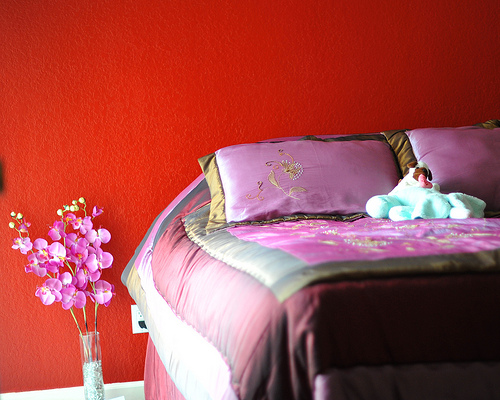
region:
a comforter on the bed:
[279, 232, 406, 294]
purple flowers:
[26, 231, 111, 298]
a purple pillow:
[222, 150, 367, 210]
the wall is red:
[69, 31, 190, 123]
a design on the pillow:
[260, 150, 326, 192]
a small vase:
[80, 333, 112, 398]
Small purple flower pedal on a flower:
[32, 281, 51, 303]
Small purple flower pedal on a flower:
[55, 291, 75, 309]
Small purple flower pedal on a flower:
[65, 289, 86, 306]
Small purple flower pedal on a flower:
[53, 270, 89, 288]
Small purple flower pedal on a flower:
[50, 242, 70, 267]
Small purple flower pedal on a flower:
[78, 213, 103, 238]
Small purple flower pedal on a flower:
[90, 249, 114, 270]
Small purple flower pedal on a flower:
[88, 279, 123, 304]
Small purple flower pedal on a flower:
[43, 225, 86, 241]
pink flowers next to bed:
[3, 197, 119, 334]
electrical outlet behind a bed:
[131, 299, 148, 334]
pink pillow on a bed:
[202, 132, 414, 228]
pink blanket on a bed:
[119, 164, 496, 398]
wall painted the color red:
[1, 3, 498, 393]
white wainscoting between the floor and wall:
[1, 380, 148, 397]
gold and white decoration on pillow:
[240, 147, 306, 202]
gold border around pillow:
[198, 148, 227, 228]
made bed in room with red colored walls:
[117, 119, 499, 399]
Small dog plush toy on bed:
[393, 159, 433, 188]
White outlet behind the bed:
[131, 303, 149, 333]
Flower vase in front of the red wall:
[8, 193, 116, 399]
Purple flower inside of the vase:
[50, 220, 68, 240]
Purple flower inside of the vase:
[68, 215, 95, 236]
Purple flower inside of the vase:
[86, 250, 112, 272]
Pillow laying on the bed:
[189, 129, 399, 231]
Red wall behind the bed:
[0, 0, 499, 394]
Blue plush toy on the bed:
[362, 185, 485, 220]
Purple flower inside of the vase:
[59, 286, 88, 309]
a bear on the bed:
[366, 160, 490, 227]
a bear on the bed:
[370, 149, 499, 233]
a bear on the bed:
[357, 155, 478, 232]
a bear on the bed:
[375, 150, 485, 235]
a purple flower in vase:
[36, 283, 64, 303]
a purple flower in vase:
[61, 288, 85, 307]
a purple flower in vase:
[93, 284, 118, 310]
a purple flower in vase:
[73, 259, 105, 281]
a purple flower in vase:
[88, 230, 121, 259]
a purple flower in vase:
[34, 238, 46, 255]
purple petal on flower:
[95, 228, 111, 244]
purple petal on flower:
[84, 227, 96, 244]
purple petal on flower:
[78, 215, 93, 234]